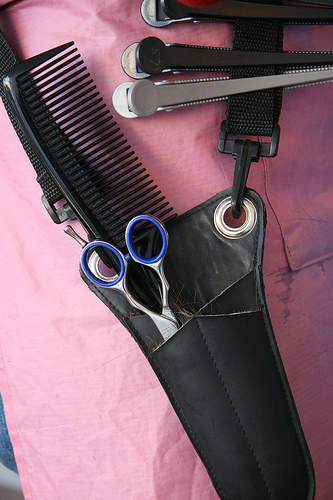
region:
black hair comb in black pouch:
[5, 38, 189, 313]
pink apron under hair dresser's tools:
[3, 2, 331, 496]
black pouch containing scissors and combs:
[76, 183, 332, 493]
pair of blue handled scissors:
[75, 210, 201, 340]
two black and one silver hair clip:
[99, 0, 332, 122]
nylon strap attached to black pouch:
[213, 1, 307, 213]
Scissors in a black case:
[78, 218, 176, 337]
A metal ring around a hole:
[215, 194, 255, 238]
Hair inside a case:
[166, 285, 204, 323]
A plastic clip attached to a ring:
[231, 138, 259, 216]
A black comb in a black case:
[3, 39, 176, 238]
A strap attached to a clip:
[221, 19, 283, 129]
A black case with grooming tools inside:
[54, 187, 318, 499]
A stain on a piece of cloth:
[274, 259, 304, 323]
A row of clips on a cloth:
[112, 0, 330, 118]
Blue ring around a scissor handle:
[127, 218, 165, 263]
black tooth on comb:
[17, 46, 77, 85]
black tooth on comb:
[24, 59, 83, 98]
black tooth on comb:
[31, 72, 90, 115]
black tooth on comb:
[40, 96, 103, 137]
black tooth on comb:
[104, 189, 162, 227]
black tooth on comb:
[95, 178, 154, 219]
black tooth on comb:
[81, 160, 142, 201]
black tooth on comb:
[70, 138, 128, 179]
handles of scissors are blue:
[71, 210, 185, 348]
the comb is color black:
[2, 36, 207, 323]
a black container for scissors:
[68, 178, 317, 496]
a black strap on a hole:
[194, 13, 299, 261]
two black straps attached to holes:
[2, 11, 309, 291]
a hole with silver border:
[210, 190, 260, 243]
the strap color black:
[223, 4, 303, 135]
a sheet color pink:
[5, 332, 131, 498]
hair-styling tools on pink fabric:
[7, 8, 324, 492]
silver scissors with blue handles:
[62, 211, 179, 340]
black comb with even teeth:
[2, 34, 177, 252]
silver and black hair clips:
[109, 2, 330, 119]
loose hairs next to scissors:
[137, 257, 223, 342]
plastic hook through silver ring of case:
[210, 183, 258, 240]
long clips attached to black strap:
[112, 0, 325, 122]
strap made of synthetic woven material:
[220, 3, 284, 137]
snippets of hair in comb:
[176, 289, 217, 309]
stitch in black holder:
[196, 345, 245, 423]